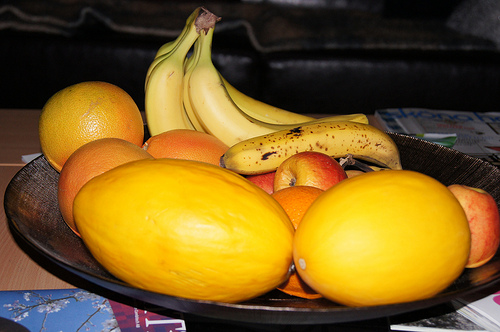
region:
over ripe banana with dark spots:
[219, 109, 414, 191]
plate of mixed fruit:
[1, 8, 496, 330]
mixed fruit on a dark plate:
[3, 9, 498, 331]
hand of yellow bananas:
[142, 6, 372, 141]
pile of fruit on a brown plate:
[14, 5, 499, 322]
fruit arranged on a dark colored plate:
[3, 6, 497, 319]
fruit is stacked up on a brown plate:
[4, 6, 492, 326]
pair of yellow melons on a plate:
[76, 151, 471, 315]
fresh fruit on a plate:
[4, 3, 496, 327]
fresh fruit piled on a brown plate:
[7, 8, 497, 320]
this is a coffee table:
[16, 65, 404, 284]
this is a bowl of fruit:
[41, 47, 424, 316]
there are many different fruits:
[49, 15, 368, 276]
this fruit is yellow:
[90, 151, 265, 276]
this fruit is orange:
[51, 86, 169, 174]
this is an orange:
[56, 71, 140, 201]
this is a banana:
[131, 20, 278, 132]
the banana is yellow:
[156, 0, 309, 157]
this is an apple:
[453, 179, 488, 216]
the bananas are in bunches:
[146, 2, 272, 134]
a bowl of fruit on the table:
[3, 75, 476, 327]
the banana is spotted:
[211, 111, 403, 166]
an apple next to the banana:
[251, 140, 341, 188]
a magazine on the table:
[366, 94, 493, 157]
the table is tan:
[0, 247, 65, 283]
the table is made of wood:
[4, 260, 65, 290]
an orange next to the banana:
[33, 63, 148, 147]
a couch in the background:
[80, 8, 469, 101]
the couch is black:
[215, 32, 457, 104]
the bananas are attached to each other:
[138, 0, 230, 117]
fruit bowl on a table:
[26, 101, 489, 313]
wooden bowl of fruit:
[9, 167, 498, 327]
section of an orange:
[34, 80, 144, 139]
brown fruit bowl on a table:
[18, 152, 499, 319]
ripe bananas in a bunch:
[136, 9, 393, 131]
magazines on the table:
[393, 97, 498, 139]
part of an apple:
[462, 182, 498, 300]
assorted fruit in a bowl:
[55, 102, 480, 316]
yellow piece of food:
[88, 164, 300, 313]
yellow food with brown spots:
[226, 111, 396, 172]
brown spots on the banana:
[273, 119, 315, 153]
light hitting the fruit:
[160, 194, 243, 279]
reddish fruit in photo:
[45, 130, 155, 210]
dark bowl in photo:
[11, 169, 101, 289]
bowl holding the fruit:
[396, 124, 494, 184]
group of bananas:
[137, 2, 257, 134]